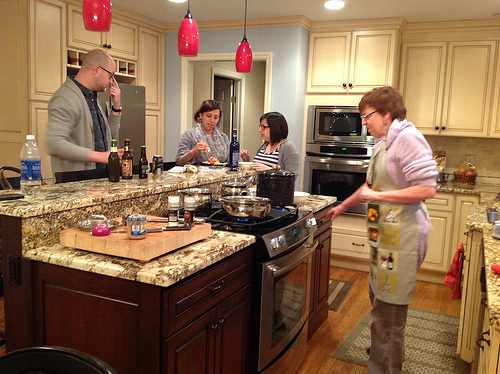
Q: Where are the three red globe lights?
A: Hanging from ceiling.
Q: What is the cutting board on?
A: A marble countertop.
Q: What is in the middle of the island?
A: An oven.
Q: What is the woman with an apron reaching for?
A: Stove handle.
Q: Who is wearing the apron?
A: The woman with a pink shirt.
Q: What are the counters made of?
A: Marble.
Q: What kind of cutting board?
A: Thick.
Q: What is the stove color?
A: Silver and black.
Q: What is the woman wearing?
A: An apron.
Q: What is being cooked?
A: Food.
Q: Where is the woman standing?
A: By the stove.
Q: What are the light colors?
A: Red.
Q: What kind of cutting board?
A: Wooden.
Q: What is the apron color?
A: Tan.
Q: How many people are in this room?
A: Four.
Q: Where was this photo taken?
A: A kitchen.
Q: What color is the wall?
A: Blue.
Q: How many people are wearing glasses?
A: Three.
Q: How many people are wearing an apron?
A: One.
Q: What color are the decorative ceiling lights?
A: Red.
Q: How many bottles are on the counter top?
A: Five.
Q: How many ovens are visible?
A: Two.